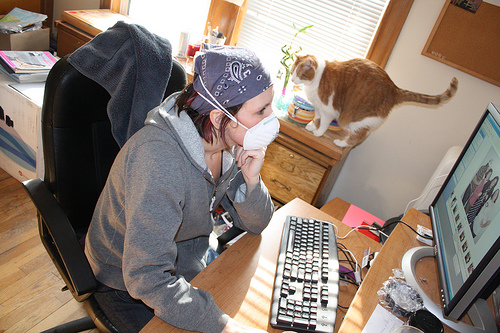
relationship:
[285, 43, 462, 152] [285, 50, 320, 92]
cat with head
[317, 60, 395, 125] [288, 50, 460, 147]
body on cat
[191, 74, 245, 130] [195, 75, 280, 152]
strap on face mask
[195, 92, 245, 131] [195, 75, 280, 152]
strap on face mask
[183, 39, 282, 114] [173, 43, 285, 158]
handkerchief on head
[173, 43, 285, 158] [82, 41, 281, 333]
head on person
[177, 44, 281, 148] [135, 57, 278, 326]
head on person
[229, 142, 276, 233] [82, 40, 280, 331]
hand on person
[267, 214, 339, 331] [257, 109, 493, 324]
computer keyborad for computer